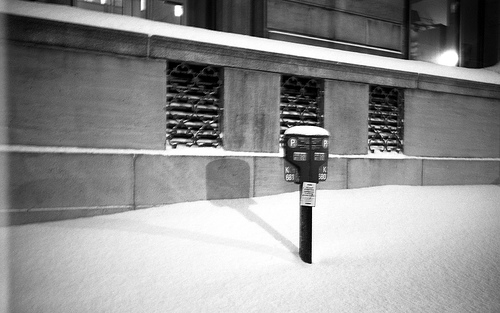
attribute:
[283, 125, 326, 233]
parking meter — in snow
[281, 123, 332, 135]
snow — on meter, white, on edges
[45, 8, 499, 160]
building — cement, behind meter, concrete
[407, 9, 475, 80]
window — silver, rectangle, on building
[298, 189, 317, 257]
pole — black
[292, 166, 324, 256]
meter — black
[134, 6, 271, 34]
sign — black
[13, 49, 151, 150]
wall — gray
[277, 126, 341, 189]
sign — for parking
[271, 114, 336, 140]
top of meter — snow covered